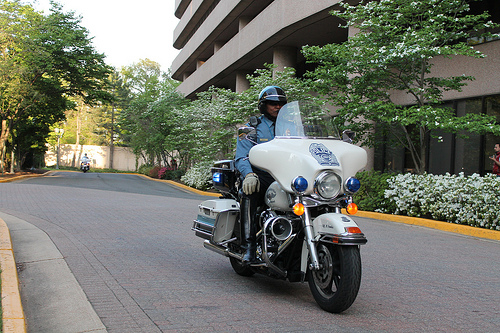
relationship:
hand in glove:
[236, 172, 263, 196] [229, 170, 267, 197]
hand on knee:
[240, 172, 262, 195] [239, 183, 261, 203]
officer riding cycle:
[230, 85, 312, 269] [192, 100, 367, 315]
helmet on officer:
[257, 83, 287, 119] [234, 70, 309, 197]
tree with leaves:
[0, 0, 104, 172] [19, 42, 54, 100]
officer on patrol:
[230, 85, 312, 269] [222, 72, 402, 310]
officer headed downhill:
[230, 85, 315, 273] [77, 170, 227, 304]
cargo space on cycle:
[193, 199, 237, 246] [191, 71, 395, 311]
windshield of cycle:
[275, 97, 341, 142] [191, 100, 368, 315]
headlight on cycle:
[316, 170, 343, 202] [191, 100, 368, 315]